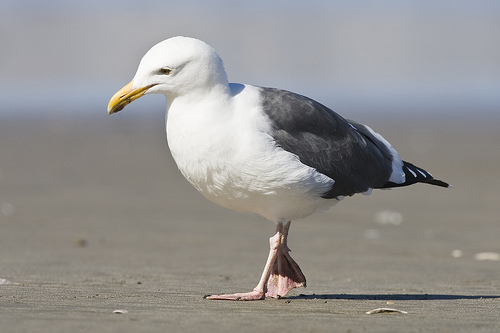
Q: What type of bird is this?
A: Gull.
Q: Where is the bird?
A: On the beach.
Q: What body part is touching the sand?
A: Feet.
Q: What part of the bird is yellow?
A: Beak.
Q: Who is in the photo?
A: Nobody.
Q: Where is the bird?
A: On the beach.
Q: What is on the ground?
A: Sand.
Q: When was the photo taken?
A: Daytime.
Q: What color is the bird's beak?
A: Yellow.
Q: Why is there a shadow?
A: It is sunny.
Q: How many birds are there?
A: One.